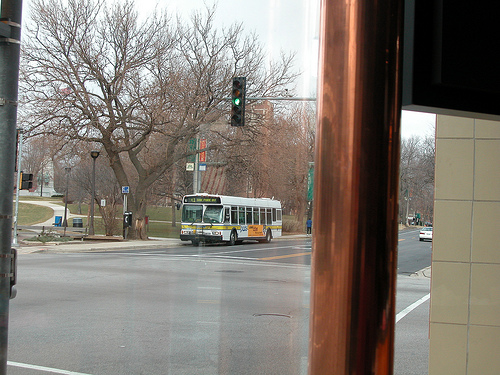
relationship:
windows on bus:
[223, 203, 282, 224] [180, 193, 282, 246]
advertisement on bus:
[239, 223, 268, 236] [168, 185, 308, 250]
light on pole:
[178, 229, 193, 235] [88, 160, 98, 235]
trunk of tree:
[123, 200, 148, 240] [16, 0, 301, 240]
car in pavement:
[417, 225, 433, 242] [8, 215, 433, 374]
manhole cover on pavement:
[254, 312, 292, 323] [8, 215, 433, 374]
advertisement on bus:
[239, 223, 268, 236] [180, 189, 293, 250]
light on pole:
[88, 149, 98, 159] [86, 157, 95, 237]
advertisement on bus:
[228, 223, 270, 241] [180, 193, 282, 246]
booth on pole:
[121, 211, 133, 239] [114, 183, 130, 235]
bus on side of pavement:
[180, 193, 282, 246] [8, 215, 433, 374]